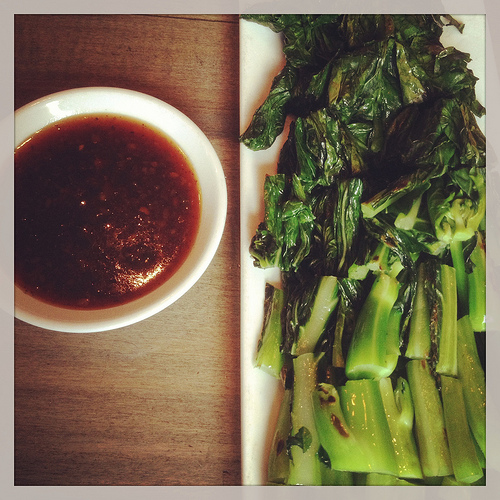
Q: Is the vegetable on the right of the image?
A: Yes, the vegetable is on the right of the image.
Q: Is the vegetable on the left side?
A: No, the vegetable is on the right of the image.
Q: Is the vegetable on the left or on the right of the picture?
A: The vegetable is on the right of the image.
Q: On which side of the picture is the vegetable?
A: The vegetable is on the right of the image.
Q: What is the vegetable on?
A: The vegetable is on the plate.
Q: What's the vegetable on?
A: The vegetable is on the plate.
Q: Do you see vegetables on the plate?
A: Yes, there is a vegetable on the plate.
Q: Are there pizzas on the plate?
A: No, there is a vegetable on the plate.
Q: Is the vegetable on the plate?
A: Yes, the vegetable is on the plate.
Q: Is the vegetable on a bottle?
A: No, the vegetable is on the plate.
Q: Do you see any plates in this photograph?
A: Yes, there is a plate.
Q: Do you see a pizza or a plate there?
A: Yes, there is a plate.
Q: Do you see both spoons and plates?
A: No, there is a plate but no spoons.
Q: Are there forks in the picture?
A: No, there are no forks.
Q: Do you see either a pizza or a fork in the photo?
A: No, there are no forks or pizzas.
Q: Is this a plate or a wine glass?
A: This is a plate.